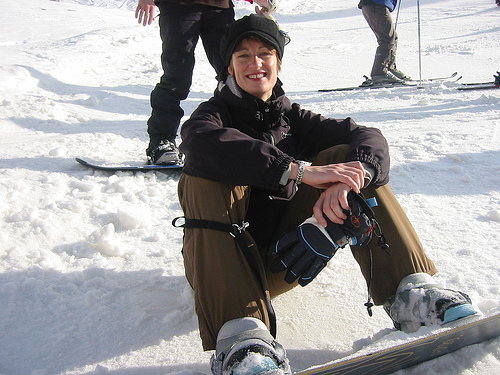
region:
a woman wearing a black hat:
[205, 17, 315, 99]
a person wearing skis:
[328, 5, 425, 98]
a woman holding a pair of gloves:
[196, 22, 329, 296]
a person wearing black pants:
[92, 2, 241, 163]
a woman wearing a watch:
[216, 16, 322, 205]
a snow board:
[55, 137, 192, 187]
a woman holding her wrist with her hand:
[214, 15, 366, 225]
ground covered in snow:
[14, 34, 224, 282]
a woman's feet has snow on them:
[222, 255, 496, 373]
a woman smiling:
[215, 15, 296, 103]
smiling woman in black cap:
[167, 15, 319, 115]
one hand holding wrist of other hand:
[250, 145, 390, 220]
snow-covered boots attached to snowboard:
[190, 267, 487, 367]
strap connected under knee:
[156, 206, 291, 346]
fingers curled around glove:
[240, 195, 382, 295]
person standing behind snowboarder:
[55, 10, 301, 185]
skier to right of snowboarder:
[230, 16, 480, 101]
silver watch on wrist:
[276, 141, 316, 191]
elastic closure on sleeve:
[326, 145, 391, 190]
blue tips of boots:
[419, 279, 486, 336]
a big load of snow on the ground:
[1, 8, 137, 155]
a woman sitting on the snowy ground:
[163, 19, 484, 364]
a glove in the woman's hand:
[265, 170, 371, 291]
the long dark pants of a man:
[130, 10, 236, 160]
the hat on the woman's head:
[221, 11, 286, 56]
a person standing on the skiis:
[356, 0, 409, 86]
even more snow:
[6, 172, 193, 356]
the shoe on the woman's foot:
[391, 278, 471, 330]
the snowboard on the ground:
[86, 145, 172, 173]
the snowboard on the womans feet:
[279, 317, 486, 373]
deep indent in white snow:
[48, 228, 135, 273]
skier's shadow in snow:
[30, 60, 142, 138]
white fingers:
[120, 2, 171, 32]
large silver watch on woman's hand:
[284, 150, 334, 217]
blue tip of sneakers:
[438, 301, 498, 326]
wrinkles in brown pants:
[383, 239, 455, 282]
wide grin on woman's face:
[235, 64, 312, 107]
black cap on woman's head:
[213, 2, 321, 54]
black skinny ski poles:
[400, 1, 449, 76]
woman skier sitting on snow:
[130, 24, 482, 371]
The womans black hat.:
[222, 8, 294, 47]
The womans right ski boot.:
[201, 321, 279, 368]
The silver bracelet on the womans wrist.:
[294, 160, 308, 189]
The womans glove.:
[270, 192, 391, 284]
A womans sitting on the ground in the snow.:
[175, 13, 471, 369]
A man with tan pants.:
[357, 0, 411, 85]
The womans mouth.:
[244, 74, 271, 81]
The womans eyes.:
[235, 51, 275, 59]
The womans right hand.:
[317, 163, 369, 186]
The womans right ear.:
[225, 60, 233, 82]